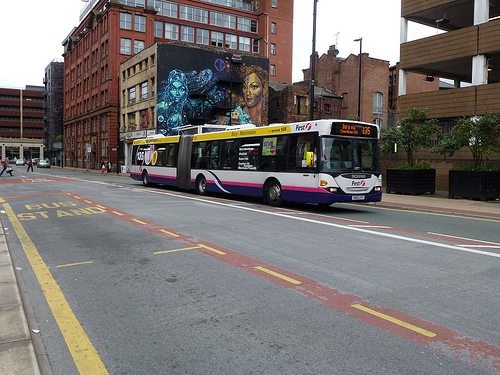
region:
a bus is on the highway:
[137, 117, 404, 282]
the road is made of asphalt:
[126, 269, 265, 329]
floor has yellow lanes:
[29, 177, 120, 252]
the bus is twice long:
[165, 126, 387, 252]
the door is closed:
[161, 133, 213, 232]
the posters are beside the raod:
[166, 47, 273, 117]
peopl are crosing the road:
[15, 144, 48, 172]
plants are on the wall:
[388, 101, 484, 162]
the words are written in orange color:
[341, 109, 378, 136]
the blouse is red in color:
[23, 150, 39, 168]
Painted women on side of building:
[156, 42, 269, 135]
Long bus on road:
[127, 119, 381, 209]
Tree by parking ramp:
[378, 105, 442, 167]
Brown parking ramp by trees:
[396, 55, 499, 166]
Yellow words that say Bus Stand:
[16, 197, 105, 222]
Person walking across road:
[0, 156, 18, 181]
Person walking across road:
[23, 155, 35, 173]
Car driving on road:
[33, 157, 52, 167]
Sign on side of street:
[83, 142, 93, 172]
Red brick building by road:
[60, 55, 135, 173]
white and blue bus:
[143, 119, 356, 198]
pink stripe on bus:
[142, 173, 353, 210]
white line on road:
[136, 183, 499, 277]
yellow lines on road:
[54, 183, 492, 353]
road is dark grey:
[377, 242, 482, 351]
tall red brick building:
[62, 32, 126, 171]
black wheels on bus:
[195, 171, 356, 204]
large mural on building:
[164, 50, 266, 143]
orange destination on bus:
[332, 112, 379, 147]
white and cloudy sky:
[318, 1, 398, 59]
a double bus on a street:
[111, 112, 398, 202]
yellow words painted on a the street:
[0, 185, 104, 239]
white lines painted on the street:
[169, 183, 455, 251]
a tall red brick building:
[78, 5, 128, 170]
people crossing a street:
[0, 152, 42, 183]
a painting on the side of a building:
[138, 50, 275, 121]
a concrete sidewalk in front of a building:
[53, 163, 102, 173]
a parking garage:
[419, 8, 471, 127]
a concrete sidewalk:
[371, 191, 482, 218]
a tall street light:
[348, 26, 368, 128]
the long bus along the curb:
[126, 119, 380, 207]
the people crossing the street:
[0, 153, 44, 180]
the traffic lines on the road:
[119, 206, 437, 344]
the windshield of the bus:
[322, 133, 379, 178]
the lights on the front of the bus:
[313, 175, 383, 201]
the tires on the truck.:
[194, 172, 286, 204]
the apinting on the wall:
[155, 38, 268, 128]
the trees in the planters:
[379, 107, 499, 168]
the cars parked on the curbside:
[29, 147, 48, 169]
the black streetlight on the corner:
[347, 34, 369, 117]